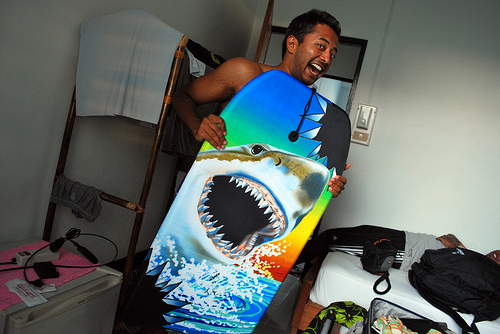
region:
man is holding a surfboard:
[195, 18, 359, 330]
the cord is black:
[40, 232, 125, 289]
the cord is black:
[2, 193, 163, 297]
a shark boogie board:
[157, 48, 342, 330]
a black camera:
[349, 224, 413, 305]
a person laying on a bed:
[299, 193, 499, 323]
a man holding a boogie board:
[198, 13, 397, 331]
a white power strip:
[11, 234, 118, 329]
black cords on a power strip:
[13, 203, 129, 306]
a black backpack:
[406, 215, 493, 311]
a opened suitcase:
[357, 292, 452, 332]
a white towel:
[78, 10, 208, 150]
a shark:
[166, 124, 346, 279]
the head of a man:
[259, 10, 361, 95]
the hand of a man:
[194, 112, 242, 166]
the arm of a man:
[159, 25, 290, 142]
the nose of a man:
[313, 42, 339, 66]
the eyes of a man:
[309, 30, 376, 61]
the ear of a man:
[284, 15, 312, 60]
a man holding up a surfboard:
[102, 13, 415, 279]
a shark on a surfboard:
[180, 42, 425, 262]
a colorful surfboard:
[116, 63, 480, 322]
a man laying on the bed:
[114, 68, 489, 307]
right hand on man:
[195, 108, 240, 186]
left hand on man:
[335, 164, 364, 239]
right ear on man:
[282, 29, 297, 46]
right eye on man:
[316, 39, 331, 55]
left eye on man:
[329, 41, 335, 56]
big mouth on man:
[307, 59, 322, 76]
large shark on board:
[209, 119, 347, 309]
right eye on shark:
[244, 141, 286, 176]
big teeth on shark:
[237, 171, 309, 255]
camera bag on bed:
[361, 219, 403, 297]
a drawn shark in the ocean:
[158, 140, 330, 282]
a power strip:
[1, 242, 63, 269]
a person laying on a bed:
[310, 220, 499, 273]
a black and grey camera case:
[359, 235, 394, 293]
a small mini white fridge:
[1, 260, 132, 332]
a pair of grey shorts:
[47, 172, 107, 222]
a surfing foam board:
[130, 69, 352, 332]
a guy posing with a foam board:
[125, 6, 352, 332]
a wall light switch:
[351, 104, 376, 144]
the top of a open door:
[251, 0, 369, 102]